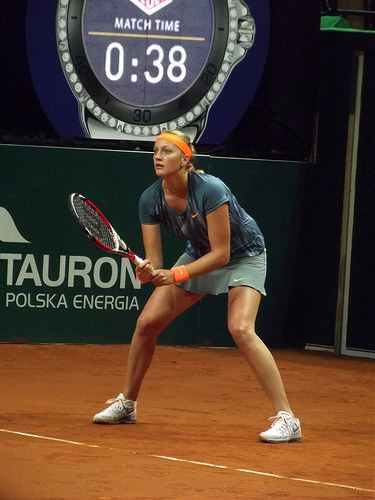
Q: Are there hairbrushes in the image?
A: No, there are no hairbrushes.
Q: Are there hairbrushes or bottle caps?
A: No, there are no hairbrushes or bottle caps.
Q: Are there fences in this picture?
A: No, there are no fences.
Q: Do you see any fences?
A: No, there are no fences.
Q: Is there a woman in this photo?
A: Yes, there is a woman.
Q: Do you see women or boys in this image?
A: Yes, there is a woman.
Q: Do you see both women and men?
A: No, there is a woman but no men.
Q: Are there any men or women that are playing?
A: Yes, the woman is playing.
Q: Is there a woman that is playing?
A: Yes, there is a woman that is playing.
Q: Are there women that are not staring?
A: Yes, there is a woman that is playing.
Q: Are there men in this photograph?
A: No, there are no men.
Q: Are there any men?
A: No, there are no men.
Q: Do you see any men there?
A: No, there are no men.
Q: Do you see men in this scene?
A: No, there are no men.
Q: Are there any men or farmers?
A: No, there are no men or farmers.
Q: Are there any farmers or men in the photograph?
A: No, there are no men or farmers.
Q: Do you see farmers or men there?
A: No, there are no men or farmers.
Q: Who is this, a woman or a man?
A: This is a woman.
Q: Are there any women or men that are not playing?
A: No, there is a woman but she is playing.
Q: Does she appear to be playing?
A: Yes, the woman is playing.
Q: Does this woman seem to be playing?
A: Yes, the woman is playing.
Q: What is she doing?
A: The woman is playing.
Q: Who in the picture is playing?
A: The woman is playing.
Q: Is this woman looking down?
A: No, the woman is playing.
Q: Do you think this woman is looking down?
A: No, the woman is playing.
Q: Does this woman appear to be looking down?
A: No, the woman is playing.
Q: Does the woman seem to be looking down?
A: No, the woman is playing.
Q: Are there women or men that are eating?
A: No, there is a woman but she is playing.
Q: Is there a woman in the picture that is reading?
A: No, there is a woman but she is playing.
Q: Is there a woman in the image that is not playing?
A: No, there is a woman but she is playing.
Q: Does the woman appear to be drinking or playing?
A: The woman is playing.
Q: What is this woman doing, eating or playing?
A: The woman is playing.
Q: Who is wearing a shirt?
A: The woman is wearing a shirt.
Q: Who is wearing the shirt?
A: The woman is wearing a shirt.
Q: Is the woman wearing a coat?
A: No, the woman is wearing a shirt.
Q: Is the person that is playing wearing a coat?
A: No, the woman is wearing a shirt.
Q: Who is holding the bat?
A: The woman is holding the bat.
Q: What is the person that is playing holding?
A: The woman is holding the bat.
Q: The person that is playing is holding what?
A: The woman is holding the bat.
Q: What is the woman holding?
A: The woman is holding the bat.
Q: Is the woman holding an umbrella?
A: No, the woman is holding the bat.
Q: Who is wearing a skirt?
A: The woman is wearing a skirt.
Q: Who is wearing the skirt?
A: The woman is wearing a skirt.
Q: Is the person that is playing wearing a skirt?
A: Yes, the woman is wearing a skirt.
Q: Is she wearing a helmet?
A: No, the woman is wearing a skirt.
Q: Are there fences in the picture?
A: No, there are no fences.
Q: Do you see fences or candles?
A: No, there are no fences or candles.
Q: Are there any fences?
A: No, there are no fences.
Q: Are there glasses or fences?
A: No, there are no fences or glasses.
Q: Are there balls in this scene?
A: No, there are no balls.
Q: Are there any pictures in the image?
A: No, there are no pictures.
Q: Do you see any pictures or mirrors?
A: No, there are no pictures or mirrors.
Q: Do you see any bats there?
A: Yes, there is a bat.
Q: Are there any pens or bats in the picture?
A: Yes, there is a bat.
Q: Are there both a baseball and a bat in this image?
A: No, there is a bat but no baseballs.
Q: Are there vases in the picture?
A: No, there are no vases.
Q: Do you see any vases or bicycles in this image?
A: No, there are no vases or bicycles.